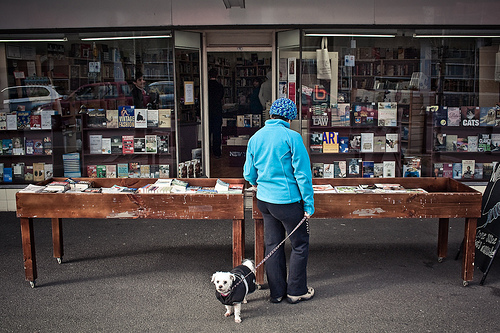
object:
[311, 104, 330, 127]
books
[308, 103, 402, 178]
shelf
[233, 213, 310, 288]
dog leash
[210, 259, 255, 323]
dog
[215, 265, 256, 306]
coat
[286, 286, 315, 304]
shoe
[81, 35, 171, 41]
light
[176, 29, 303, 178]
doorway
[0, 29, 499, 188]
book store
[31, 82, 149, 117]
reflection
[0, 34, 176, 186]
window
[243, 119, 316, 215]
jacket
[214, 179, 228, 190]
books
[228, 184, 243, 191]
books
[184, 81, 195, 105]
sign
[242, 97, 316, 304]
person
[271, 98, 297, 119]
blue hat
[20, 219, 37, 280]
leg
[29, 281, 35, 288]
wheel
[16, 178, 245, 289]
stands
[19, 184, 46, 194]
books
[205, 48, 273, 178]
door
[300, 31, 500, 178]
window